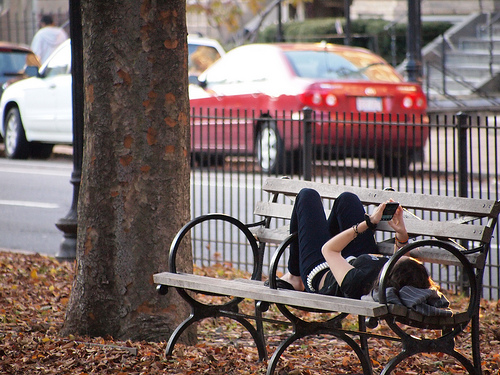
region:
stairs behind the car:
[422, 18, 497, 98]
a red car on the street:
[190, 36, 430, 171]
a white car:
[5, 40, 86, 135]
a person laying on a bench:
[175, 175, 470, 356]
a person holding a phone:
[275, 191, 440, 302]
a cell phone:
[380, 201, 395, 222]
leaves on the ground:
[30, 307, 420, 372]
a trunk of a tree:
[81, 25, 191, 325]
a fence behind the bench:
[190, 101, 495, 258]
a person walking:
[30, 15, 57, 46]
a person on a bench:
[260, 179, 439, 314]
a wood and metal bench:
[152, 174, 499, 370]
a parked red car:
[193, 38, 430, 173]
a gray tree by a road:
[69, 6, 194, 338]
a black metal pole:
[53, 1, 92, 267]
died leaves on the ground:
[0, 253, 63, 371]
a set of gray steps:
[433, 13, 497, 98]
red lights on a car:
[307, 93, 429, 108]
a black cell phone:
[377, 196, 400, 223]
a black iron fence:
[193, 104, 310, 243]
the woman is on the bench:
[229, 155, 431, 334]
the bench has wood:
[192, 166, 399, 363]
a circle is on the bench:
[174, 203, 281, 335]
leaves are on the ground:
[15, 260, 95, 352]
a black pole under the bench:
[229, 313, 299, 360]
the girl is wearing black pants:
[285, 205, 355, 332]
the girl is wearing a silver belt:
[294, 232, 429, 348]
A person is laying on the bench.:
[286, 207, 436, 324]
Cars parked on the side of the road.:
[31, 25, 390, 169]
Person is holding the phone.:
[376, 195, 411, 227]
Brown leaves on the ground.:
[6, 318, 213, 374]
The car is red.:
[186, 28, 444, 178]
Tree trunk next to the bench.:
[53, 7, 200, 292]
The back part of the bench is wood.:
[258, 177, 474, 249]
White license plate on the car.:
[344, 84, 397, 118]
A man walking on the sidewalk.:
[16, 6, 68, 74]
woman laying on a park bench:
[267, 184, 454, 318]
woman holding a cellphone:
[379, 194, 407, 227]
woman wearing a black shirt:
[324, 235, 389, 302]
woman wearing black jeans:
[275, 188, 374, 283]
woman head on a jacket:
[367, 257, 447, 325]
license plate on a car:
[356, 90, 388, 117]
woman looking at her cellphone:
[348, 199, 428, 236]